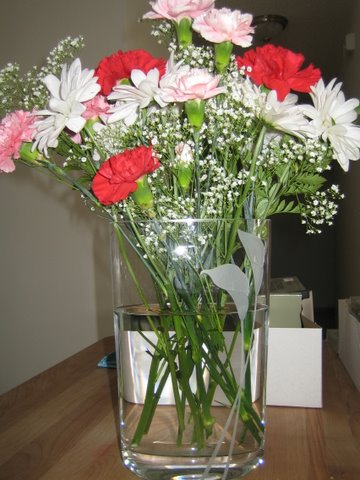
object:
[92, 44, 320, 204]
flowers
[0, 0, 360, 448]
bouqet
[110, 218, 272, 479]
vase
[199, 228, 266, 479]
design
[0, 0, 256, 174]
flowers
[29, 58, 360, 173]
flowers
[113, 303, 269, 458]
water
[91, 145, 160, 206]
flower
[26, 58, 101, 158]
flower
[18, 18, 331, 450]
stems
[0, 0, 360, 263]
flowers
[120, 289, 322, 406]
box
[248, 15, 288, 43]
light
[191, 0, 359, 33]
ceiling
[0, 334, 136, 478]
lines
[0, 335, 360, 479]
wood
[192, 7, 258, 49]
flower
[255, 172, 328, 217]
leaves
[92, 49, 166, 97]
carnation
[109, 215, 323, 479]
items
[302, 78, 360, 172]
daisy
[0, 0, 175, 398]
wall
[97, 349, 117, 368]
fabric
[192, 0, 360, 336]
passageway